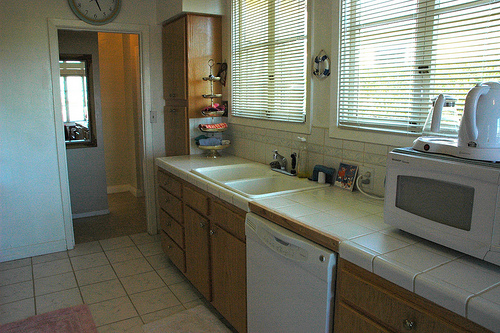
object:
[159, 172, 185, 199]
drawers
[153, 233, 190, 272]
drawers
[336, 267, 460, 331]
drawers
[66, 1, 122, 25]
clock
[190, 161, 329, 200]
sink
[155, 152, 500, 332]
cabinet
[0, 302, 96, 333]
mat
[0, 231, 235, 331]
floor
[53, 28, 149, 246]
door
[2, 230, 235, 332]
ground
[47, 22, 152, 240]
doorway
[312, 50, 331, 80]
life preserver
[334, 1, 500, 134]
closed windows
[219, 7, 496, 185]
wall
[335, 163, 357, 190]
picture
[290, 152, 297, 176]
faucet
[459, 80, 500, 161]
coffee maker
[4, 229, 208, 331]
floor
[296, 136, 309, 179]
bottle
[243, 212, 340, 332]
dishwasher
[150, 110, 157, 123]
switch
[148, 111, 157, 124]
light switch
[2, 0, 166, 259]
wall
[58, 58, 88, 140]
mirror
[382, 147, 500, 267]
microwave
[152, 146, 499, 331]
counter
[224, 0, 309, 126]
windows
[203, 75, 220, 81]
tray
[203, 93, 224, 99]
tray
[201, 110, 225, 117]
tray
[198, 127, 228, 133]
tray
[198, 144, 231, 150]
tray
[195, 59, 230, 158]
stand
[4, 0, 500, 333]
kitchen